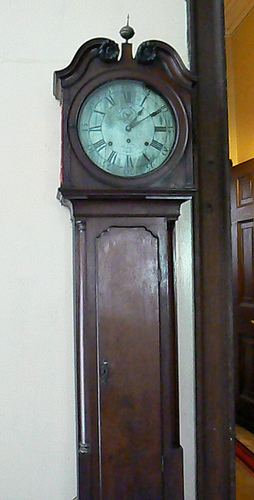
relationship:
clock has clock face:
[52, 29, 200, 498] [77, 78, 176, 179]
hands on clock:
[126, 107, 160, 130] [71, 73, 180, 184]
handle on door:
[100, 360, 107, 384] [79, 216, 177, 497]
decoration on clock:
[116, 22, 134, 41] [52, 29, 200, 498]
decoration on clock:
[98, 40, 118, 61] [52, 29, 200, 498]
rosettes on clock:
[132, 39, 159, 62] [52, 29, 200, 498]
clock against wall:
[52, 16, 200, 500] [4, 46, 50, 267]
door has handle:
[76, 215, 184, 499] [102, 359, 107, 384]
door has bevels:
[231, 158, 253, 432] [236, 175, 252, 205]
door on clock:
[76, 215, 184, 499] [55, 7, 207, 497]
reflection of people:
[136, 244, 190, 294] [237, 368, 240, 373]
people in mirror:
[237, 368, 240, 373] [226, 301, 245, 466]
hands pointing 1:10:
[126, 107, 160, 130] [136, 88, 165, 134]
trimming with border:
[222, 1, 244, 35] [227, 2, 249, 34]